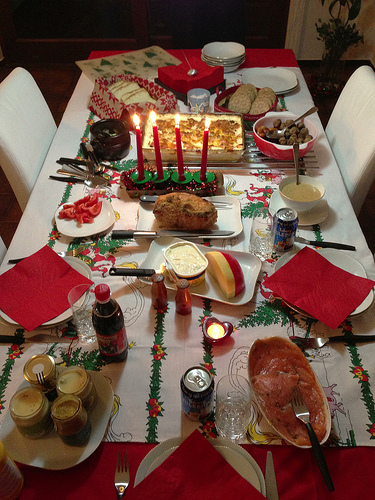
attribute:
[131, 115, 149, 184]
candle — red, tall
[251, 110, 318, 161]
bowl — red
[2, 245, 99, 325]
napkin — red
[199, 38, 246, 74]
bowls — stacked, white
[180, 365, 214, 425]
can — aluminum, blue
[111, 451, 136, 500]
fork — silver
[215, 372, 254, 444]
glass — clear, empty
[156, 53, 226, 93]
napkins — red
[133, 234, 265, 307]
plate — rectangular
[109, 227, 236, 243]
knife — black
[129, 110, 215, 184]
candles — scented, lit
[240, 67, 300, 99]
plates — stacked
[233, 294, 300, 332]
tree — green